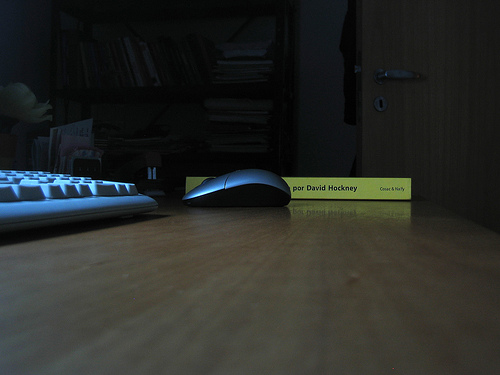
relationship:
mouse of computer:
[194, 175, 303, 211] [10, 75, 127, 230]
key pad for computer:
[1, 164, 155, 235] [10, 75, 127, 230]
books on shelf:
[72, 31, 273, 159] [46, 8, 276, 176]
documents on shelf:
[82, 2, 250, 146] [46, 8, 276, 176]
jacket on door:
[328, 7, 358, 120] [357, 4, 498, 205]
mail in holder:
[47, 130, 101, 169] [49, 139, 123, 194]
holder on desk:
[49, 139, 123, 194] [26, 159, 445, 374]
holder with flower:
[49, 139, 123, 194] [4, 93, 72, 127]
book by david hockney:
[151, 176, 421, 200] [290, 180, 361, 196]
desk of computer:
[26, 159, 445, 374] [10, 75, 127, 230]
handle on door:
[372, 70, 425, 80] [357, 4, 498, 205]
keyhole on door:
[374, 96, 387, 113] [357, 4, 498, 205]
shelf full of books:
[46, 8, 276, 176] [72, 31, 273, 159]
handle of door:
[372, 70, 425, 80] [357, 4, 498, 205]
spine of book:
[177, 178, 412, 201] [151, 176, 421, 200]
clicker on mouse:
[190, 178, 227, 207] [194, 175, 303, 211]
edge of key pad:
[78, 196, 142, 219] [1, 164, 161, 233]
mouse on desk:
[194, 175, 303, 211] [0, 160, 500, 374]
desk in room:
[0, 160, 500, 374] [8, 16, 471, 374]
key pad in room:
[1, 164, 161, 233] [8, 16, 471, 374]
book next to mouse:
[151, 176, 421, 200] [194, 175, 303, 211]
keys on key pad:
[1, 169, 81, 194] [1, 164, 161, 233]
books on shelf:
[72, 31, 273, 159] [46, 8, 287, 171]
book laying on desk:
[151, 176, 421, 200] [26, 159, 445, 374]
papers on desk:
[43, 135, 114, 174] [26, 159, 445, 374]